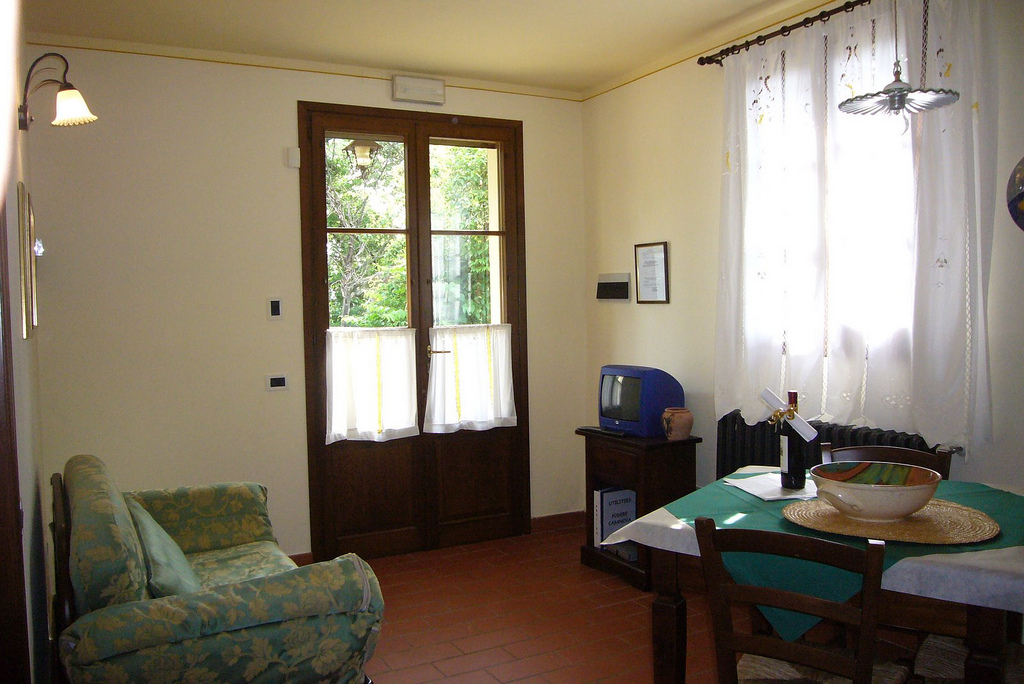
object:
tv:
[598, 364, 684, 437]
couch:
[54, 454, 387, 684]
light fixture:
[17, 52, 99, 130]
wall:
[0, 0, 45, 682]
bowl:
[809, 461, 942, 523]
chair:
[695, 517, 888, 684]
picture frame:
[634, 241, 670, 304]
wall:
[592, 0, 1024, 492]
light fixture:
[838, 0, 961, 118]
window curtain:
[715, 0, 1006, 449]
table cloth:
[662, 468, 1024, 643]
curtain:
[325, 327, 420, 446]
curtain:
[422, 323, 519, 434]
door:
[297, 100, 420, 564]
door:
[425, 112, 531, 552]